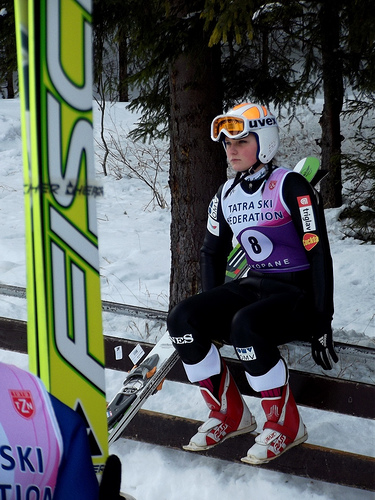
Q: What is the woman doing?
A: Sitting.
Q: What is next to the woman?
A: Skis.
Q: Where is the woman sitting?
A: On a ledge.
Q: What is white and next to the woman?
A: The skis.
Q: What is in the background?
A: A tree.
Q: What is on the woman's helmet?
A: Goggles.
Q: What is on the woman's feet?
A: Red and white ski boots.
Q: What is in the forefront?
A: Snow.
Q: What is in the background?
A: Snow.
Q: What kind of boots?
A: Ski boots.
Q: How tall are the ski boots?
A: Calf length.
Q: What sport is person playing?
A: Skiing.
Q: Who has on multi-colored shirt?
A: Girl skier.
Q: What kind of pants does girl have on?
A: Ski pants.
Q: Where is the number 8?
A: On girl's race bib.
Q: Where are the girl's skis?
A: Beside her on the right.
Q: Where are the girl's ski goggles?
A: On her safety helmet.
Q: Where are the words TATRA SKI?
A: On girl's race bib.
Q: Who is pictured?
A: A woman.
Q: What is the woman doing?
A: Sitting.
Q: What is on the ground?
A: Snow.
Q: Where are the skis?
A: Next to the woman.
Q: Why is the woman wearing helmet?
A: For protection.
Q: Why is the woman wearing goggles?
A: For protection.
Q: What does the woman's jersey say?
A: Tatra Ski Federation.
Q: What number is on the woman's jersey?
A: 8.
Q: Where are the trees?
A: Behind the woman.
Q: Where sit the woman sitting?
A: On a fence.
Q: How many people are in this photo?
A: One.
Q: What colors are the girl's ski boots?
A: Red and white.